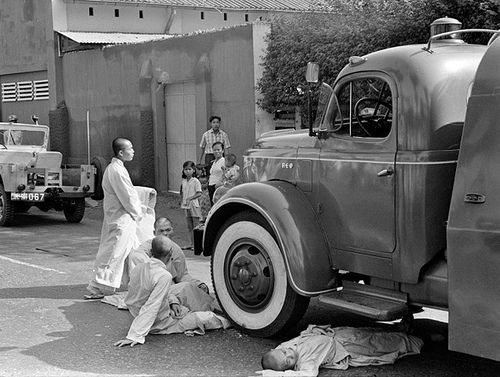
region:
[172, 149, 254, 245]
Children looking on at scene.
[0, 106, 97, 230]
Jeep type vehicle in background.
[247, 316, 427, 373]
Man laying under the truck.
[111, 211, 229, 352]
Men in white sitting on the ground.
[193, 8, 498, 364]
Large older truck parked.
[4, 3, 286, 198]
Large building in the background.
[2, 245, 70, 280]
White lines on the ground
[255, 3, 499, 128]
Trees in the background.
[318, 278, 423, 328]
Running board on the truck.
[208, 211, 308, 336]
White walled tires on the truck.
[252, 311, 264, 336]
tire is black and white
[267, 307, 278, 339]
tire is black and white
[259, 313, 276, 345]
tire is black and white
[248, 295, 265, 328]
tire is black and white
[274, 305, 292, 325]
tire is black and white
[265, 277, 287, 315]
tire is black and white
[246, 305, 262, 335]
tire is black and white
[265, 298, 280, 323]
tire is black and white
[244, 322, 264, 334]
tire is black and white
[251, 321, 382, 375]
A man laying under the truck.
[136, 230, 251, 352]
People sitting by the truck.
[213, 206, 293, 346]
The tire has thick white walls.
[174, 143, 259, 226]
Children standing in the street and looking.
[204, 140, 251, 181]
A woman holding a baby.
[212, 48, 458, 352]
A truck parked on the street.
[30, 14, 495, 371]
The photo is taken in black and white.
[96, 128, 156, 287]
The person is wearing a white robe.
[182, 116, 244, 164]
The man is wearing a pleated shirt.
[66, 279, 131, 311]
The person is wearing flip flops.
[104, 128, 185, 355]
Asian monks look at car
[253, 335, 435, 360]
Monk lying on ground underneath car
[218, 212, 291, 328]
Front left wheel of automobile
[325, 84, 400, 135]
Left window of car is opened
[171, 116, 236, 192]
Family in background looks on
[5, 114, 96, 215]
Another vehicle in background of photo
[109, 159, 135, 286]
Monk is wearing white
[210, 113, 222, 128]
Man in background has black hair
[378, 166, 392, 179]
Small silver handle of door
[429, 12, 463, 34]
Small circular area on top of car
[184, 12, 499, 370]
an old truck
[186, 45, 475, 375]
a man is laying under the truck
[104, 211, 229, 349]
two men are sitting on the ground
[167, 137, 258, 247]
a woman standing with children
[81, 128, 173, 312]
a man is walking on the road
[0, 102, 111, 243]
a jeep beside the building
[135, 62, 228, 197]
a door beside the man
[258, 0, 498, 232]
bushes behind the truck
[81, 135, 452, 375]
the men are wearing robes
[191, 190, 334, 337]
the truck has a white wall tire